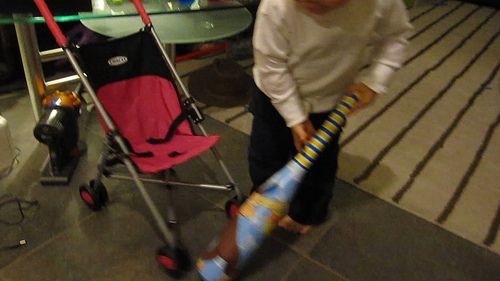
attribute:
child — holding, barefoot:
[249, 2, 414, 236]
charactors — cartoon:
[200, 181, 285, 274]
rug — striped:
[171, 1, 500, 255]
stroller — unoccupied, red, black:
[35, 1, 253, 272]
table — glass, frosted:
[3, 2, 258, 22]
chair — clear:
[80, 11, 254, 44]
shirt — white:
[252, 0, 413, 140]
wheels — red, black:
[79, 180, 112, 211]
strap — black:
[116, 111, 196, 157]